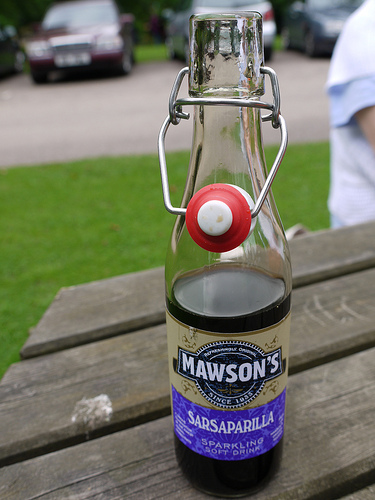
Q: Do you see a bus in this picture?
A: No, there are no buses.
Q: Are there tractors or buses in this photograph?
A: No, there are no buses or tractors.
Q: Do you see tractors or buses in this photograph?
A: No, there are no buses or tractors.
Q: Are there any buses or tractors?
A: No, there are no buses or tractors.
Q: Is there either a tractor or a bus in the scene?
A: No, there are no buses or tractors.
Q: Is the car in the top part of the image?
A: Yes, the car is in the top of the image.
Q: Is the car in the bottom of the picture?
A: No, the car is in the top of the image.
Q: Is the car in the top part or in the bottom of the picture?
A: The car is in the top of the image.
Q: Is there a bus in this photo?
A: No, there are no buses.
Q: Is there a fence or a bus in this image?
A: No, there are no buses or fences.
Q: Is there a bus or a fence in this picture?
A: No, there are no buses or fences.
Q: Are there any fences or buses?
A: No, there are no buses or fences.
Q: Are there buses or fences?
A: No, there are no buses or fences.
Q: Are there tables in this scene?
A: Yes, there is a table.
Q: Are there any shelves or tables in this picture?
A: Yes, there is a table.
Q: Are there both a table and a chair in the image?
A: No, there is a table but no chairs.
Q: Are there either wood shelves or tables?
A: Yes, there is a wood table.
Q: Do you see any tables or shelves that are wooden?
A: Yes, the table is wooden.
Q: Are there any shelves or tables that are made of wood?
A: Yes, the table is made of wood.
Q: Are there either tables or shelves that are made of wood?
A: Yes, the table is made of wood.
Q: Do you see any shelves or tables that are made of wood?
A: Yes, the table is made of wood.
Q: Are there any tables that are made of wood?
A: Yes, there is a table that is made of wood.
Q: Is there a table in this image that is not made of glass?
A: Yes, there is a table that is made of wood.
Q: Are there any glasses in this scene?
A: No, there are no glasses.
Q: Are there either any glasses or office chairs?
A: No, there are no glasses or office chairs.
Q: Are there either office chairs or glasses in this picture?
A: No, there are no glasses or office chairs.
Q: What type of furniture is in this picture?
A: The furniture is a table.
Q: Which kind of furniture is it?
A: The piece of furniture is a table.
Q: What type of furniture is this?
A: This is a table.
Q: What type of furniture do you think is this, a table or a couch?
A: This is a table.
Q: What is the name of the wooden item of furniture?
A: The piece of furniture is a table.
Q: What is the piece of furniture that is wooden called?
A: The piece of furniture is a table.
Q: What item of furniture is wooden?
A: The piece of furniture is a table.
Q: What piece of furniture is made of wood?
A: The piece of furniture is a table.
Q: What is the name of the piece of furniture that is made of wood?
A: The piece of furniture is a table.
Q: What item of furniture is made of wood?
A: The piece of furniture is a table.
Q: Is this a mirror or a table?
A: This is a table.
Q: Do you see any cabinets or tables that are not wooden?
A: No, there is a table but it is wooden.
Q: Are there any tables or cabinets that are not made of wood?
A: No, there is a table but it is made of wood.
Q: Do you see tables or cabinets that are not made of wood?
A: No, there is a table but it is made of wood.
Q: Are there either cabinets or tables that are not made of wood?
A: No, there is a table but it is made of wood.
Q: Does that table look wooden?
A: Yes, the table is wooden.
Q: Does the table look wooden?
A: Yes, the table is wooden.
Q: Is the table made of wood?
A: Yes, the table is made of wood.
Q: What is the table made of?
A: The table is made of wood.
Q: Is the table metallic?
A: No, the table is wooden.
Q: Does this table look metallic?
A: No, the table is wooden.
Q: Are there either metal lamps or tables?
A: No, there is a table but it is wooden.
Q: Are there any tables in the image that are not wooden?
A: No, there is a table but it is wooden.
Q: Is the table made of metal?
A: No, the table is made of wood.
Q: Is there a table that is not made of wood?
A: No, there is a table but it is made of wood.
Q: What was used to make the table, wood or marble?
A: The table is made of wood.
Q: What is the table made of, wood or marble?
A: The table is made of wood.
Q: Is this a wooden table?
A: Yes, this is a wooden table.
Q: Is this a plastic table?
A: No, this is a wooden table.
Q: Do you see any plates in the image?
A: No, there are no plates.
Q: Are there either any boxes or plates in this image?
A: No, there are no plates or boxes.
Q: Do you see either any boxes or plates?
A: No, there are no plates or boxes.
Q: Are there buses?
A: No, there are no buses.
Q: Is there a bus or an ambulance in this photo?
A: No, there are no buses or ambulances.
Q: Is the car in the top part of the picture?
A: Yes, the car is in the top of the image.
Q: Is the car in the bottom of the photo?
A: No, the car is in the top of the image.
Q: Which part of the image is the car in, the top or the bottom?
A: The car is in the top of the image.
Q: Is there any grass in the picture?
A: Yes, there is grass.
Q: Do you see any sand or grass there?
A: Yes, there is grass.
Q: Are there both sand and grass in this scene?
A: No, there is grass but no sand.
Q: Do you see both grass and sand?
A: No, there is grass but no sand.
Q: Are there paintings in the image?
A: No, there are no paintings.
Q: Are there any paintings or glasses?
A: No, there are no paintings or glasses.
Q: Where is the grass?
A: The grass is on the ground.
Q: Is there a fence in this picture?
A: No, there are no fences.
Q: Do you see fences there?
A: No, there are no fences.